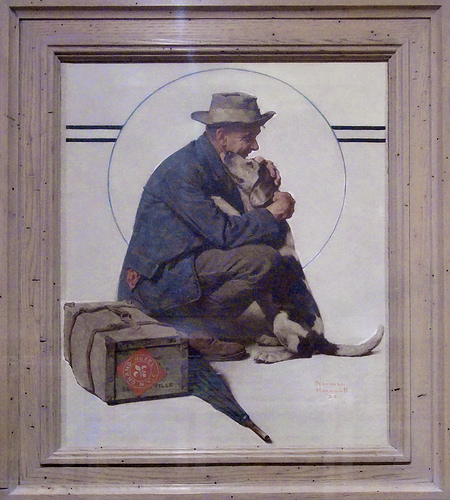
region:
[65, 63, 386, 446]
Norman Rockwell style painting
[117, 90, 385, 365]
elderly man and dog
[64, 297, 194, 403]
old trunk beside man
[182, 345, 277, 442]
blue umbrella beside man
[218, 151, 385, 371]
black and white dog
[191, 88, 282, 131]
beat up hat on man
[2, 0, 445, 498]
light wood picture frame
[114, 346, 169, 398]
red sticker on end of trunk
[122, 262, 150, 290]
red handkerchief in man's pocket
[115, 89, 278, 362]
elderly man squatting down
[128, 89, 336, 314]
man hugs dog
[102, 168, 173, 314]
rag in pocket of coat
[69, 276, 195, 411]
label on end of suitcase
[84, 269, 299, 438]
umbrella next to suitcase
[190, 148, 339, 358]
dog is black and white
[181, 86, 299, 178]
man has hat on his head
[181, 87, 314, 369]
man has brown boots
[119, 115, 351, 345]
man wearing blue coat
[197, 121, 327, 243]
dog has paws on man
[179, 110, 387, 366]
black and white dog has short tail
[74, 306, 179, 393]
this is a box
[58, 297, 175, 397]
the box is made of wood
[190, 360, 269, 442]
this is an umbrella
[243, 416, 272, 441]
the numbrella has a metalic top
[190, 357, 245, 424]
the umbrella is blue in color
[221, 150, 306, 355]
this is a dog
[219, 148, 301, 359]
the dog is black and white in color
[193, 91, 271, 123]
this is a hat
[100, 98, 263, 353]
this is a person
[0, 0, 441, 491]
this is a wooden frame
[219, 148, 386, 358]
A spotted dog standing against a man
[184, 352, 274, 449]
Blue umbrella with long point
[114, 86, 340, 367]
Older man holding a dog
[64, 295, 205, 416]
Old box with orange logo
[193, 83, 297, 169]
Hat on a older mans head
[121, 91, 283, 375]
Older man wearing a blue coat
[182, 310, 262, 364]
Worn brown boots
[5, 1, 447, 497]
Wooden picture frame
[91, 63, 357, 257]
Blue outlined circle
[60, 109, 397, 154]
Two black stripes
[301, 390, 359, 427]
part of a white background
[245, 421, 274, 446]
tip of an umbrella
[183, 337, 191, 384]
edge of a box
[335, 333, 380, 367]
tail of a dog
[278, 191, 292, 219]
right hand of a dog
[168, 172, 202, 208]
part of a blue coat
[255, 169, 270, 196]
left ear of a dog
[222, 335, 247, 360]
part of a brown shoe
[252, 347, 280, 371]
part of the dog's paw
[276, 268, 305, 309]
stomach of the dog